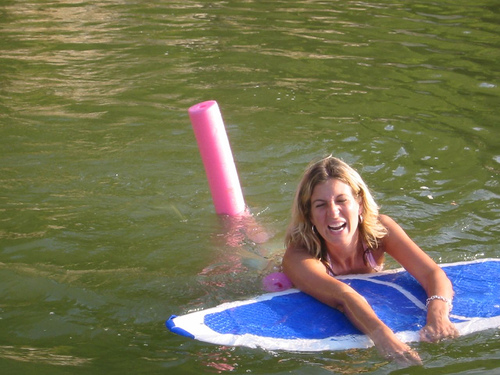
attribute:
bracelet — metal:
[424, 295, 454, 310]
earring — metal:
[311, 224, 317, 234]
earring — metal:
[358, 214, 364, 226]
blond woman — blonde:
[276, 157, 455, 361]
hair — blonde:
[286, 154, 387, 256]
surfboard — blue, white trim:
[162, 251, 497, 363]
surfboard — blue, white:
[163, 256, 498, 351]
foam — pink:
[167, 85, 278, 263]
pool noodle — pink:
[179, 99, 256, 215]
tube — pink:
[192, 98, 269, 220]